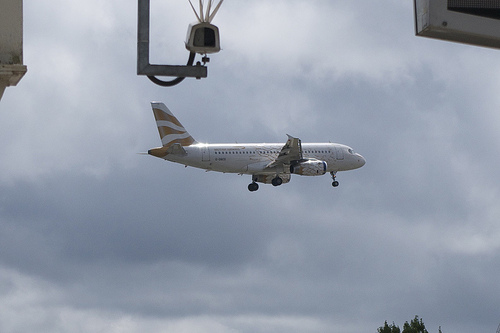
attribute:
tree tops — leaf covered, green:
[375, 314, 445, 333]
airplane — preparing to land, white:
[135, 98, 368, 195]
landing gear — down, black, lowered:
[327, 172, 343, 188]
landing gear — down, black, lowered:
[268, 175, 285, 189]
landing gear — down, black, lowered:
[246, 179, 257, 192]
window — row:
[257, 148, 287, 157]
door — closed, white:
[199, 144, 212, 164]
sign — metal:
[409, 1, 499, 55]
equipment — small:
[180, 0, 231, 62]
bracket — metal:
[134, 1, 209, 82]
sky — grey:
[1, 1, 500, 333]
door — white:
[331, 145, 349, 165]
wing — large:
[264, 133, 307, 171]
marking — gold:
[146, 107, 201, 160]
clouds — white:
[47, 2, 498, 94]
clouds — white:
[5, 211, 498, 306]